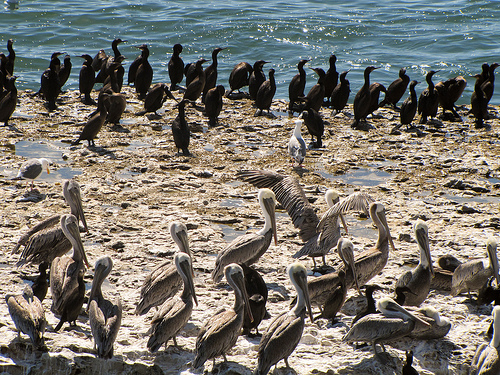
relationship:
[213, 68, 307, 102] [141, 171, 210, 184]
pelicans on beach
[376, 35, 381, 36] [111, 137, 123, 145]
water on sand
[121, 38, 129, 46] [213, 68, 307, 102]
bill of pelicans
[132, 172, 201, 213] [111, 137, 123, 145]
claw prints on sand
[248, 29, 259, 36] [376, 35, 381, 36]
reflection on water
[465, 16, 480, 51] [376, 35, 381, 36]
foam on water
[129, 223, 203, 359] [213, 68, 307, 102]
seagull near pelicans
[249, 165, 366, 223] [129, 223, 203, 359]
wings of seagull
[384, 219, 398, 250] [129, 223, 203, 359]
beak of seagull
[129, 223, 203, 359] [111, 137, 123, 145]
seagull in sand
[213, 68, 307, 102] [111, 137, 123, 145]
pelicans in sand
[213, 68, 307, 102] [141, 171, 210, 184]
pelicans at beach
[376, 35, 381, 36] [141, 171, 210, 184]
water on beach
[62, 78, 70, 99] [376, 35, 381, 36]
bubbles on water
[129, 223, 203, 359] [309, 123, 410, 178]
seagull on shore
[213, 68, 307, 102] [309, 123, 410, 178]
pelicans on shore